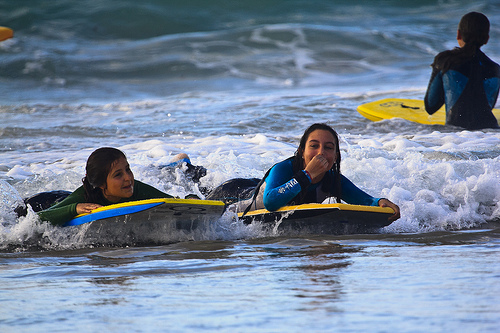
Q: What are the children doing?
A: Surfing.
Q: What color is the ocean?
A: Blue.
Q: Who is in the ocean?
A: Children.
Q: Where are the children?
A: In the ocean.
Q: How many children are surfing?
A: Three.